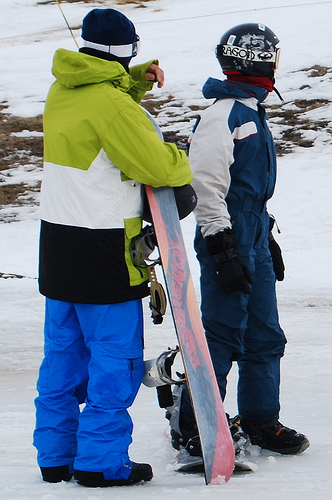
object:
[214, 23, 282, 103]
helmet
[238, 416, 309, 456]
foot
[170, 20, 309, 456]
man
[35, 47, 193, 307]
hoodie coat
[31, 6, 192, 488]
man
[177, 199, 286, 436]
pants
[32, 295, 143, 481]
pants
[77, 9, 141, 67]
beanie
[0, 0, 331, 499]
snow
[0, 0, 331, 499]
ground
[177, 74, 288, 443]
snow suit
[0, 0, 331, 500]
photo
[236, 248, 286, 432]
leg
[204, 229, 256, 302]
glove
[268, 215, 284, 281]
glove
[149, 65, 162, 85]
fingers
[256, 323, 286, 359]
knee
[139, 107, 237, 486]
board